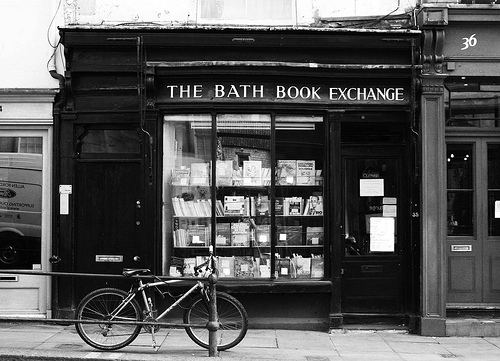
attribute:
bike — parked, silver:
[74, 243, 248, 349]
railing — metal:
[0, 268, 218, 358]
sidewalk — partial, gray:
[0, 320, 498, 361]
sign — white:
[369, 216, 394, 252]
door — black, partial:
[341, 143, 406, 312]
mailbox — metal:
[95, 254, 123, 262]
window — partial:
[0, 136, 41, 269]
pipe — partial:
[48, 70, 64, 319]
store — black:
[49, 26, 422, 330]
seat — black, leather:
[123, 267, 150, 277]